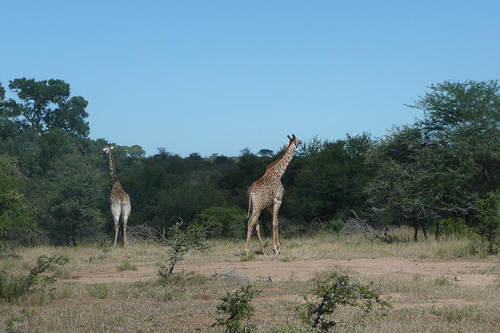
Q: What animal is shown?
A: Giraffe.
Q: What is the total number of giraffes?
A: 2.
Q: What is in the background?
A: Trees.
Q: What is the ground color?
A: Brown.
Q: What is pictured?
A: Animals.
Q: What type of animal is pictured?
A: Giraffes.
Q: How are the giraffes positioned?
A: Standing.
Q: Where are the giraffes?
A: Field.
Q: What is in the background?
A: Trees.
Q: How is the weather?
A: Clear.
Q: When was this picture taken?
A: During day hours.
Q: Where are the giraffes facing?
A: The trees.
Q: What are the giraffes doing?
A: Eating.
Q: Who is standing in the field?
A: Two giraffes.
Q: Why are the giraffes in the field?
A: For food.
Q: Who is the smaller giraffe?
A: The one on the left.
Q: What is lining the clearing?
A: Trees.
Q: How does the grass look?
A: Dry.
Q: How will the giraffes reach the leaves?
A: With their long necks.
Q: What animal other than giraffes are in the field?
A: No other animals.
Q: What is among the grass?
A: Small plants.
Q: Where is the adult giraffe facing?
A: Right.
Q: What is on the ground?
A: Dirt.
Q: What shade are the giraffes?
A: Brown and white.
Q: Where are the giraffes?
A: In the jungle.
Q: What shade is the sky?
A: Blue.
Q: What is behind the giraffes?
A: Trees.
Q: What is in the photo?
A: A giraffe.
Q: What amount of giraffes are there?
A: Two.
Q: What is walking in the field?
A: 2 giraffes.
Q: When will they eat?
A: They are eating.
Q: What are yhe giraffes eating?
A: They are eating yhe trees.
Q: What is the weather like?
A: Sunny and clear.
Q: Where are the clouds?
A: There are no clouds.